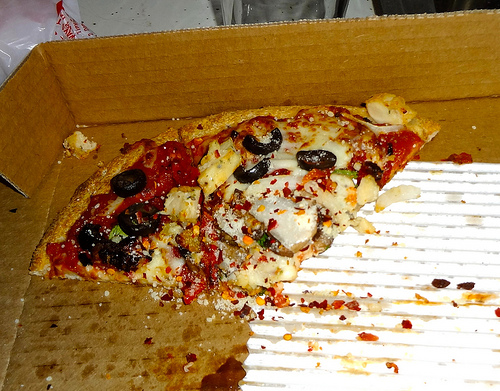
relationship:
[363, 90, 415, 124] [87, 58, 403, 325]
mushroom on pizza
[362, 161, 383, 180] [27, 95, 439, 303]
olives on pizza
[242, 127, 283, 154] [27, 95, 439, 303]
olive on pizza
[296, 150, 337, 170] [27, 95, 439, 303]
olive on pizza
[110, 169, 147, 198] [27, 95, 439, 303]
olives on pizza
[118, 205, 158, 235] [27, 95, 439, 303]
olives on pizza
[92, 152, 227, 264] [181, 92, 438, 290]
tomatoes on pizza slice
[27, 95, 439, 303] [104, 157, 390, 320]
pizza has toppings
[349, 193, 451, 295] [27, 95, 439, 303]
paper below pizza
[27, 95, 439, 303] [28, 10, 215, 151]
pizza in box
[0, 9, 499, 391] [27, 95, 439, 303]
box with pizza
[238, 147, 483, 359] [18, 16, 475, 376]
liner in box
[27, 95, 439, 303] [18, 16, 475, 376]
pizza in box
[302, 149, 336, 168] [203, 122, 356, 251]
olive on cheese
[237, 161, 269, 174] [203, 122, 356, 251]
olive on cheese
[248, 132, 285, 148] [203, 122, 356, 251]
olive on cheese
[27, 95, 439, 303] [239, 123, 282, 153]
pizza with olive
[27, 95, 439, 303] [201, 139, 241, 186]
pizza with pineapple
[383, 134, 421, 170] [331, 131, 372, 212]
sauce mixed with cheese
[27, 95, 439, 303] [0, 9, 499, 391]
pizza in a box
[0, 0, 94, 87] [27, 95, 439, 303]
bag behind pizza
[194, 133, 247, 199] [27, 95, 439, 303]
chicken on pizza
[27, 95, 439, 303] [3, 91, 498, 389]
pizza in foreground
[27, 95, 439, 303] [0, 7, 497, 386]
pizza inside a box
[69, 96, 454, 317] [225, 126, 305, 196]
pizza has olives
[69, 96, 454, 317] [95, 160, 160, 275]
pizza has olives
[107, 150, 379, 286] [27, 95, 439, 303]
toppings on top of pizza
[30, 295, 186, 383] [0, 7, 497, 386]
grease on box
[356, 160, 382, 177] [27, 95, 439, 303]
olives on pizza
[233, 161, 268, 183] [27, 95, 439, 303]
olive on pizza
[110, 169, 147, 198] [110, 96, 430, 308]
olives are on pizza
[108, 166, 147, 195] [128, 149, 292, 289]
olives are on pizza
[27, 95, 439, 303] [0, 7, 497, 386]
pizza in a box